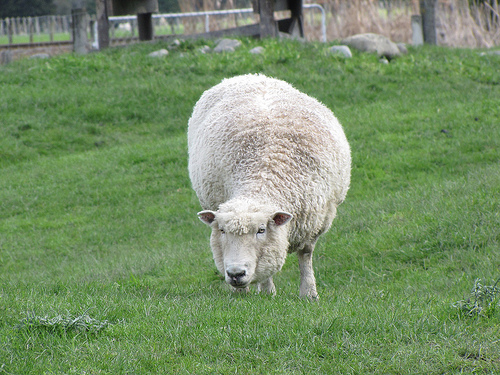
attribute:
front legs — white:
[249, 235, 321, 307]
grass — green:
[348, 238, 414, 292]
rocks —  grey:
[327, 30, 410, 63]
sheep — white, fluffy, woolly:
[185, 70, 352, 303]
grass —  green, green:
[0, 37, 497, 373]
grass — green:
[355, 171, 461, 317]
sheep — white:
[183, 70, 383, 297]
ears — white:
[191, 194, 316, 234]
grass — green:
[374, 50, 491, 372]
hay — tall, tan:
[301, 4, 497, 46]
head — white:
[197, 197, 291, 287]